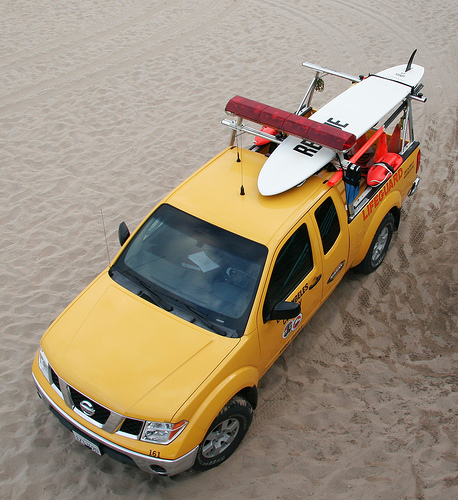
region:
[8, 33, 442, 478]
The truck is carrying a surfboard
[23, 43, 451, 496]
The truck is driving in the sand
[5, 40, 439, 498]
The truck belongs to the lifeguards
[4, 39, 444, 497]
The truck is used by the city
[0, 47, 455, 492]
The truck is used for emergency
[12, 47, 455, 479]
The truck is carrying safety gear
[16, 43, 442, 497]
The truck is painted bright yellow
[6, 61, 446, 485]
The truck is very distinctly marked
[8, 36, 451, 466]
The truck is carrying emergency lights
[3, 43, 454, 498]
The truck is using special tires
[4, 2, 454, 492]
footprints on sandy surface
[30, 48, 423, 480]
top of yellow truck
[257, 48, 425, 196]
black word on surfboard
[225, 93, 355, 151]
long red light on truck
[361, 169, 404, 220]
red word on yellow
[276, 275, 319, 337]
emblems on truck door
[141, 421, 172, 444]
headlight on front of truck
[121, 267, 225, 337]
windshield wipers on windshield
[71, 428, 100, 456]
license plate on front of truck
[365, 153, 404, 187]
life saving device on truck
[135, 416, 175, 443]
Headlight of yellow car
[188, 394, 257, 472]
Front wheel of car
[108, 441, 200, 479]
Part of front bumper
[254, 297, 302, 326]
Side view car mirror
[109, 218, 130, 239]
Side view car mirror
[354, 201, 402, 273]
Rear wheel of car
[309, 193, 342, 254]
Back window of car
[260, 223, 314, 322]
Drivers side car window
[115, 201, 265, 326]
Front windshield of car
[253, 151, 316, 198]
Part of white surfboard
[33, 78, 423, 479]
the truck on the sand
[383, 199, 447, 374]
the tracks in the sand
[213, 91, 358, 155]
the red light on the truck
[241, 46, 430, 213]
the surfboard on the truck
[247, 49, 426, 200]
the surfboard is white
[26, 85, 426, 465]
the truck is yellow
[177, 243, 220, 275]
the papers in the truck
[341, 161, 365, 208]
the fins on the truck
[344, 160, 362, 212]
the fins are blue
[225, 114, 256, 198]
the antennae on the truck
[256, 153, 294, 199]
The tip of the surfboard.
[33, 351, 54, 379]
The left headlight on the truck.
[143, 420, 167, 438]
The right headlight on the truck.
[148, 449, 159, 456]
The number 161 on the truck.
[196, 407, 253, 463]
The front tire of the tire.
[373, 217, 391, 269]
The back tire of the truck.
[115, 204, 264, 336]
The front window of the truck.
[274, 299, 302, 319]
The side view mirror on the right of the truck.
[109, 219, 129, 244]
The side mirror on the left side of the truck.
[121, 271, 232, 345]
The windshield wipers on the truck.